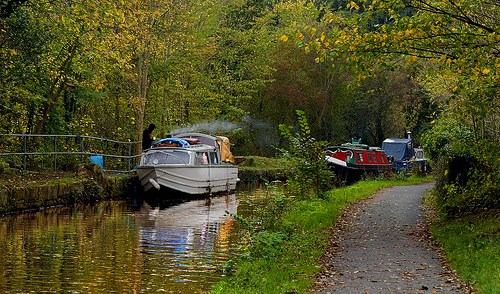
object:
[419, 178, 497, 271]
grass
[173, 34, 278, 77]
leaves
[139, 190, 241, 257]
boat reflection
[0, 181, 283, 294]
water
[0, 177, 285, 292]
river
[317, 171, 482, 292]
path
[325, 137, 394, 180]
boat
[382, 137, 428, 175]
boat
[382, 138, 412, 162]
cover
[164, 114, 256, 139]
smoke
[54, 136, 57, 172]
pole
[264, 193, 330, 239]
bush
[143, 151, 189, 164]
windshield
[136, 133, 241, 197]
boat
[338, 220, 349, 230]
leaves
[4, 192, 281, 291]
canal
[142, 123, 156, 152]
person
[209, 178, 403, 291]
grass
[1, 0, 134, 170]
tree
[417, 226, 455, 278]
leaves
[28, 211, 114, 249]
reflection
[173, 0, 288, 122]
tree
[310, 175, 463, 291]
road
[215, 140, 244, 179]
back